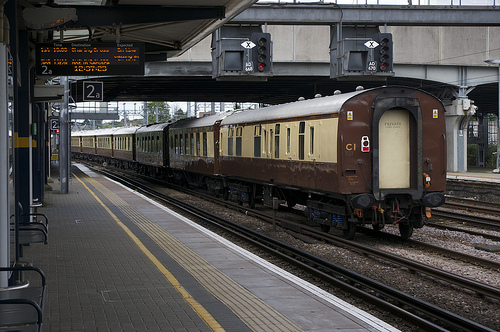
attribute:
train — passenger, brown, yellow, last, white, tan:
[74, 83, 451, 236]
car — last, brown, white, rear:
[219, 80, 449, 237]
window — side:
[234, 123, 245, 158]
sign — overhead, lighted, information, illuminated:
[36, 40, 145, 78]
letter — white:
[95, 88, 101, 100]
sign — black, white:
[80, 77, 107, 101]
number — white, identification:
[84, 84, 95, 99]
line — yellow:
[71, 172, 224, 331]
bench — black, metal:
[0, 261, 48, 330]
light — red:
[257, 62, 267, 70]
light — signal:
[377, 33, 394, 74]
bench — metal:
[14, 196, 50, 257]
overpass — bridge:
[1, 0, 500, 96]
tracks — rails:
[85, 177, 499, 331]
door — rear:
[380, 109, 412, 189]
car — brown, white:
[166, 110, 222, 196]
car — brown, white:
[133, 118, 167, 174]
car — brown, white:
[113, 123, 135, 168]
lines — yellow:
[80, 170, 299, 331]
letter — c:
[345, 140, 353, 151]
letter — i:
[351, 140, 358, 152]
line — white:
[103, 173, 397, 331]